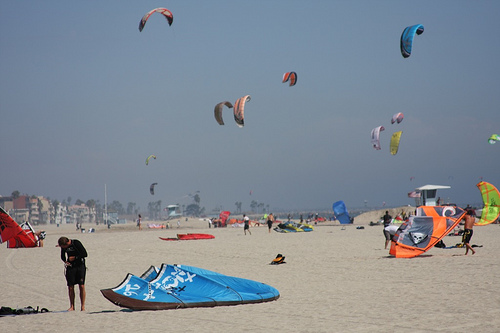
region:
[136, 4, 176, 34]
red black and white kite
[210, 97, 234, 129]
black and grey kite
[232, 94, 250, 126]
orange black and white kite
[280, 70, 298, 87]
red black and white kite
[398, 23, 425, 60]
a black and blue kite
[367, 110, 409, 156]
three kites in the sky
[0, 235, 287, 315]
a man preparing his kite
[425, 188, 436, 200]
window on a lifeguard booth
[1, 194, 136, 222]
a stretch of buildings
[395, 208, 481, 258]
a man holding a kite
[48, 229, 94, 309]
Person wearing black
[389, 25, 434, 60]
Blue kite in sky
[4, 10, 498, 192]
Sky is blue and hazy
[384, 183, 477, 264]
Orange kites in background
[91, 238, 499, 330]
Ground is sandy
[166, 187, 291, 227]
Large objects in distance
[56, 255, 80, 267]
Hands are white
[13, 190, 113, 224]
Buildings behind person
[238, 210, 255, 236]
Man wearing white outfit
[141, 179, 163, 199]
Kite in distance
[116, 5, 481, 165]
Paragliders are in the sky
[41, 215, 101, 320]
Man is standing on the beach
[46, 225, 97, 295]
Man is wearing a black shirt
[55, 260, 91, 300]
Man is wearing shorts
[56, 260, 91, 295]
Shorts are black in color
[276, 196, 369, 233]
An ocean is in the blackground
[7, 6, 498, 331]
Photo was taken in the daytime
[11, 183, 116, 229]
Buildings are in the background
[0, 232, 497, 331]
Sand is tan colored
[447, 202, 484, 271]
Shirtless man in the background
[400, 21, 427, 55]
Blue and black parachute in sky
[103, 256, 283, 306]
Blue parachute behind man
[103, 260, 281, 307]
Blue parachute on sand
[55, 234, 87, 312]
Man wearing black shorts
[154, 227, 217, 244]
Red parachute on sand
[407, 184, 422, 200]
USA flag by lifeguard house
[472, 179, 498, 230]
Yellow and orange parachute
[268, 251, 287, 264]
Backpack sitting on sand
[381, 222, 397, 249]
Man bending over is wearing a white shirt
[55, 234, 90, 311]
Man wearing black shirt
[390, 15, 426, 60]
Blue and black parachute in the sky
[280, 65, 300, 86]
Orange black and white parachute in the sky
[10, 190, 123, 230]
Hotels and motels along the beach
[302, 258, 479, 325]
Sandy beach by the ocean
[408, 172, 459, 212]
Lifeguard tower on a beach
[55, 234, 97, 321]
Man fiddling with something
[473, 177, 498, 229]
Parachute on the ground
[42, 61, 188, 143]
Ominous looking sky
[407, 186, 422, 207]
American flag on a lifeguard tower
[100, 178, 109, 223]
Utility pole in the background